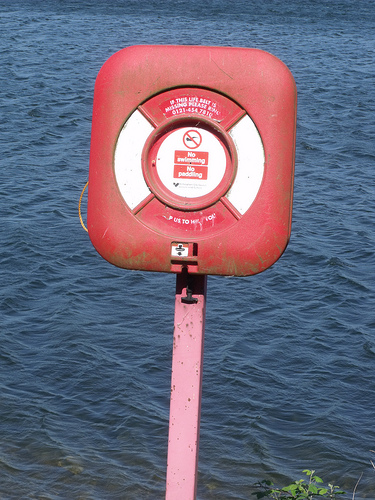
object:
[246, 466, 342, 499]
bush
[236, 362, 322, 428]
ripples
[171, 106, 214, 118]
phone number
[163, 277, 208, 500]
paint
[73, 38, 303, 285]
stand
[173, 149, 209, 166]
signs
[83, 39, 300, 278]
sign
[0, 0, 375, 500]
lake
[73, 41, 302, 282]
life preserver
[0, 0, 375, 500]
water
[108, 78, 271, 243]
warning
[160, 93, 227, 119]
lettering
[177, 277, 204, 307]
latch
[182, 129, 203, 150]
sign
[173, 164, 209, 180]
sign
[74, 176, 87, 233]
cord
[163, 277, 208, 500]
arm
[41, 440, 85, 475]
rock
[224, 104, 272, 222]
portion